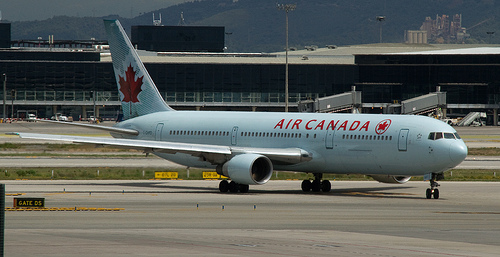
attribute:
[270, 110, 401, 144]
logo — red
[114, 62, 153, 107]
leaf — red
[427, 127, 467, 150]
windows — small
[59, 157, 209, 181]
grass — green